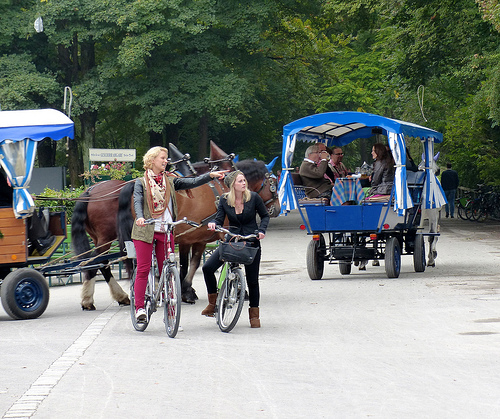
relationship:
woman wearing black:
[222, 174, 265, 249] [227, 221, 240, 230]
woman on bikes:
[201, 170, 271, 329] [142, 247, 241, 318]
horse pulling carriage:
[181, 199, 185, 201] [301, 208, 377, 231]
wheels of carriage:
[300, 239, 420, 281] [301, 208, 377, 231]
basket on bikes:
[211, 238, 254, 264] [142, 247, 241, 318]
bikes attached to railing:
[142, 247, 241, 318] [451, 159, 499, 223]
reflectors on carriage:
[297, 214, 391, 245] [301, 208, 377, 231]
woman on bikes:
[222, 174, 265, 249] [142, 247, 241, 318]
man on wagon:
[295, 131, 329, 187] [383, 198, 434, 233]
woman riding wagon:
[222, 174, 265, 249] [383, 198, 434, 233]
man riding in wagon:
[295, 131, 329, 187] [383, 198, 434, 233]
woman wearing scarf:
[222, 174, 265, 249] [149, 174, 175, 213]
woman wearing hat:
[222, 174, 265, 249] [316, 141, 329, 151]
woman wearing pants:
[222, 174, 265, 249] [152, 293, 155, 296]